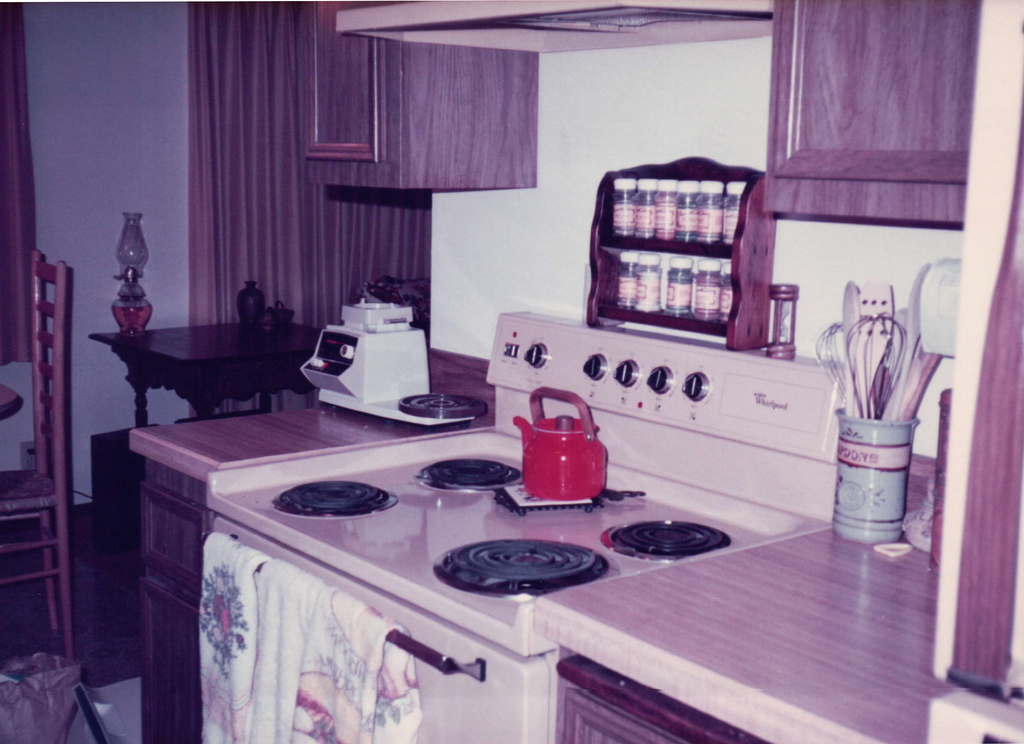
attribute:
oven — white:
[212, 244, 826, 722]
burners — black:
[288, 453, 755, 620]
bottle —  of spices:
[651, 180, 673, 241]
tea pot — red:
[509, 385, 605, 496]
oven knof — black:
[685, 368, 705, 403]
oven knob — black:
[644, 363, 666, 394]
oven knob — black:
[644, 366, 666, 390]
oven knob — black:
[682, 370, 711, 409]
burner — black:
[445, 532, 595, 582]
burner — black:
[604, 521, 726, 563]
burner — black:
[276, 471, 389, 511]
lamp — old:
[106, 210, 145, 331]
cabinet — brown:
[298, 20, 541, 202]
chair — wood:
[13, 247, 80, 673]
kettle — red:
[512, 385, 601, 500]